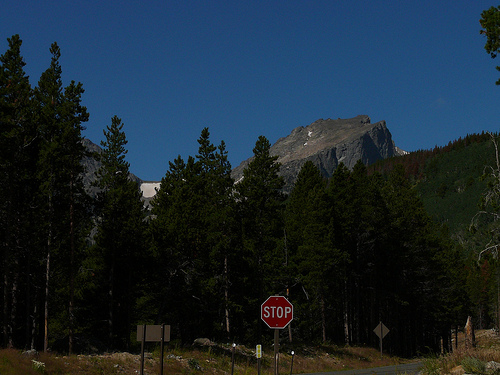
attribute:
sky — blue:
[81, 30, 433, 118]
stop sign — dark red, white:
[257, 290, 295, 330]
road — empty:
[317, 356, 432, 373]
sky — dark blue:
[148, 37, 371, 132]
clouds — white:
[141, 31, 296, 93]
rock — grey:
[223, 113, 398, 191]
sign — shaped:
[251, 294, 301, 330]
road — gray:
[283, 360, 434, 373]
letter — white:
[262, 305, 269, 319]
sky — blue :
[92, 20, 424, 108]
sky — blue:
[8, 0, 498, 155]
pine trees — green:
[35, 70, 481, 248]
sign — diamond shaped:
[368, 318, 395, 341]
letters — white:
[263, 305, 291, 324]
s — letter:
[261, 304, 271, 322]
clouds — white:
[138, 151, 194, 216]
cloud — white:
[216, 45, 316, 99]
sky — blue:
[111, 70, 358, 143]